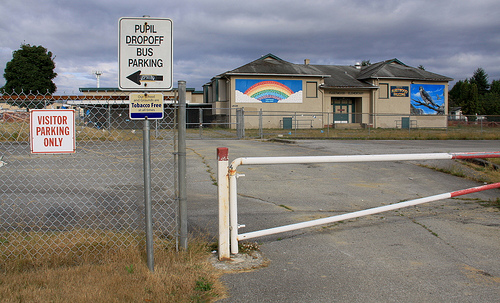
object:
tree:
[447, 66, 500, 121]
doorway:
[331, 97, 361, 123]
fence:
[0, 80, 187, 269]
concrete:
[1, 138, 497, 303]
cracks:
[409, 219, 490, 276]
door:
[333, 100, 348, 123]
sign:
[335, 105, 347, 113]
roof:
[230, 53, 454, 87]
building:
[79, 52, 455, 129]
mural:
[410, 84, 446, 116]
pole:
[216, 147, 230, 261]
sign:
[30, 108, 76, 154]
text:
[126, 22, 164, 67]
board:
[117, 17, 174, 92]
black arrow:
[126, 70, 163, 85]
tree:
[0, 39, 57, 109]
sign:
[129, 93, 165, 120]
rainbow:
[244, 81, 295, 101]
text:
[37, 115, 70, 146]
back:
[449, 53, 460, 100]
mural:
[235, 79, 304, 103]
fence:
[215, 146, 499, 260]